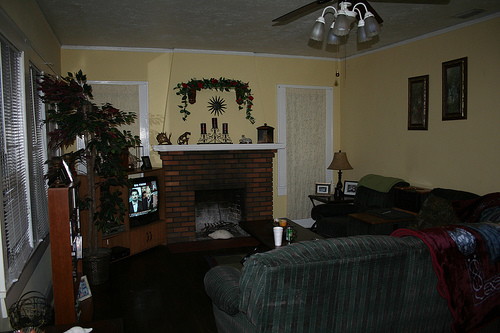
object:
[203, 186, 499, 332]
couch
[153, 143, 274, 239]
fire place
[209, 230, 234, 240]
ashes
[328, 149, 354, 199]
lamp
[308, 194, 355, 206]
table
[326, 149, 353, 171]
shade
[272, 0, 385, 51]
ceiling fan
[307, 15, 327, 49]
lights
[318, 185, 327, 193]
photo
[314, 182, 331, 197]
frame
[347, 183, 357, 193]
photo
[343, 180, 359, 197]
frame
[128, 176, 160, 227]
television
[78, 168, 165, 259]
entertainment center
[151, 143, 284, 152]
mantel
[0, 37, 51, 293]
window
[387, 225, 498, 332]
blanket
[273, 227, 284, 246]
cup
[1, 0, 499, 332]
room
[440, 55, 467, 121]
picture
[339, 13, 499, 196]
wall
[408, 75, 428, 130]
picture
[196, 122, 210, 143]
candles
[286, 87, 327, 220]
curtain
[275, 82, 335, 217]
window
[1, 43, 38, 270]
blinds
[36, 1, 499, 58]
ceiling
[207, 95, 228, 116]
sun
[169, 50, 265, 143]
wall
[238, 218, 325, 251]
table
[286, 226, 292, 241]
soda can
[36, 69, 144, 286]
tee